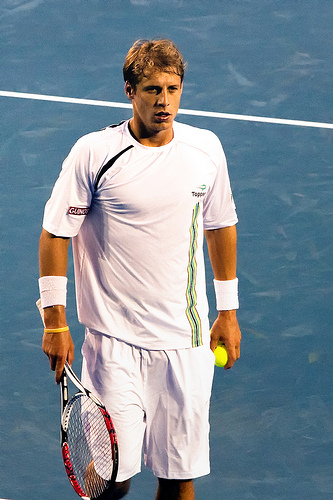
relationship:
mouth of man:
[155, 109, 173, 119] [39, 37, 241, 499]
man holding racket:
[23, 37, 248, 498] [34, 299, 120, 499]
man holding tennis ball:
[23, 37, 248, 498] [210, 342, 229, 370]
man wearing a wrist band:
[39, 37, 241, 499] [204, 260, 244, 348]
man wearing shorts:
[23, 37, 248, 498] [80, 328, 215, 480]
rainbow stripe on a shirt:
[186, 200, 204, 346] [98, 195, 160, 301]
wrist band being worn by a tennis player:
[212, 275, 240, 311] [35, 38, 239, 498]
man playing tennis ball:
[23, 37, 248, 498] [213, 342, 229, 367]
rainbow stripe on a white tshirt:
[186, 200, 204, 346] [41, 120, 238, 350]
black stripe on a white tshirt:
[94, 142, 133, 194] [41, 120, 238, 350]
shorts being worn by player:
[80, 328, 215, 480] [30, 33, 266, 497]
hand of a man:
[42, 327, 74, 385] [39, 37, 241, 499]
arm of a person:
[38, 135, 96, 323] [86, 18, 222, 420]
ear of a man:
[122, 77, 136, 102] [39, 37, 241, 499]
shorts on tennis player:
[80, 328, 215, 480] [35, 38, 239, 498]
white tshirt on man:
[41, 120, 238, 350] [39, 37, 241, 499]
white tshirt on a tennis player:
[23, 115, 252, 263] [35, 38, 239, 498]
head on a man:
[121, 36, 185, 131] [39, 37, 241, 499]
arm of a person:
[204, 227, 243, 370] [52, 17, 238, 497]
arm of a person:
[37, 223, 76, 382] [52, 17, 238, 497]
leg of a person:
[155, 476, 196, 499] [33, 20, 220, 337]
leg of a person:
[81, 457, 131, 498] [33, 20, 220, 337]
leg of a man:
[155, 387, 197, 498] [39, 37, 241, 499]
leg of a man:
[81, 457, 131, 498] [39, 37, 241, 499]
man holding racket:
[39, 37, 241, 499] [57, 364, 120, 498]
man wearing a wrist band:
[39, 37, 241, 499] [212, 275, 240, 311]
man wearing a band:
[39, 37, 241, 499] [39, 273, 68, 306]